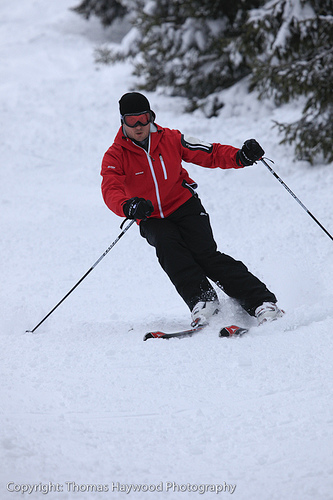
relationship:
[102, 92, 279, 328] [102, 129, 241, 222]
man wearing jacket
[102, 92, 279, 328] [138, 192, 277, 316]
man wearing pants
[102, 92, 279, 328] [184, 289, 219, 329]
man wearing boot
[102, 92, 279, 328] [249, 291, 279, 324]
man wearing boot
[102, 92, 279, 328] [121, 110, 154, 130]
man wearing googles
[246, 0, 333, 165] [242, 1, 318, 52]
tree with snow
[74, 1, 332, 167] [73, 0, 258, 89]
snow covered tree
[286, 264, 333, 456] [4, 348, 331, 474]
snow on ground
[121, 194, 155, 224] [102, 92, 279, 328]
glove on man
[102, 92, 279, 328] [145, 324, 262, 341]
man on skies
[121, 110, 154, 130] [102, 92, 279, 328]
googles on man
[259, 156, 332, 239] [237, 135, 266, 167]
pole in hand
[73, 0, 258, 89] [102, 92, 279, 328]
tree behind man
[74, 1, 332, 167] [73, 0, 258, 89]
snow on tree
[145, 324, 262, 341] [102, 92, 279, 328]
skies on man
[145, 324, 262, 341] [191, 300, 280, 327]
skies on feet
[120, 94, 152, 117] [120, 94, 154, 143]
cap on head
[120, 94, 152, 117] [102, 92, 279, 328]
cap on man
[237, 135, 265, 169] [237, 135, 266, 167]
glove on hand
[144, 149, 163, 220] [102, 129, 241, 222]
zipper on jacket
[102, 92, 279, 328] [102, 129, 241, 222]
man in jacket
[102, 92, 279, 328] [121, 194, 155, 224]
man wearing glove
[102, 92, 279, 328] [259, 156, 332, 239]
man holding pole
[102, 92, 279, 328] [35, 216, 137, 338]
man holding pole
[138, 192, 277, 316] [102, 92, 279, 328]
pants on man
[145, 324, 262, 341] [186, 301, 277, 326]
skies on feet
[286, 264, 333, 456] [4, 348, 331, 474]
snow covering ground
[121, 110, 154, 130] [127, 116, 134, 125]
googles on eye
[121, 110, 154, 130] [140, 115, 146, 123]
googles on eye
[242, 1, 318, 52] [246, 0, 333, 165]
snow on tree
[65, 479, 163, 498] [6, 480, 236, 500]
name in letters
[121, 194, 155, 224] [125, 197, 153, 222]
glove on hand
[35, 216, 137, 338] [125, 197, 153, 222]
pole in hand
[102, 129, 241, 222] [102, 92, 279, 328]
jacket on man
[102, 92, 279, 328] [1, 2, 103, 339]
man on hill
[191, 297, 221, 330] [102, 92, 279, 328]
foot of man